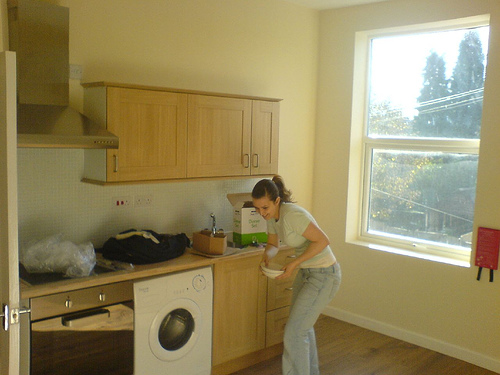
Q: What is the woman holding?
A: Bowl.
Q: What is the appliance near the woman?
A: Washer.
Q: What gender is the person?
A: Female.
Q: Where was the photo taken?
A: In a room.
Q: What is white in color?
A: The washer.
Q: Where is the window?
A: Behind the lady.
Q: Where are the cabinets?
A: Above the lady.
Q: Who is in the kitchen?
A: A girl.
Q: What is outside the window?
A: Trees.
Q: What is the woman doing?
A: Smiling.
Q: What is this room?
A: Kitchen.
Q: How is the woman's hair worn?
A: Up in a ponytail.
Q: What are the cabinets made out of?
A: Wood.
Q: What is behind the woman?
A: Window.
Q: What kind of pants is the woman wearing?
A: Jeans.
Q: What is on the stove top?
A: Plastic bags.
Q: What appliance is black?
A: Oven and stove.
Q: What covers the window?
A: Nothing.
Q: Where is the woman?
A: In the kitchen.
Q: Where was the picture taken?
A: In a house.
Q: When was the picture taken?
A: Daytime.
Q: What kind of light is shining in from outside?
A: Sunlight.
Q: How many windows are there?
A: One.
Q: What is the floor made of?
A: Wood.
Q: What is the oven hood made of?
A: Metal.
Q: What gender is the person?
A: Female.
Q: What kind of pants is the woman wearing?
A: Jeans.